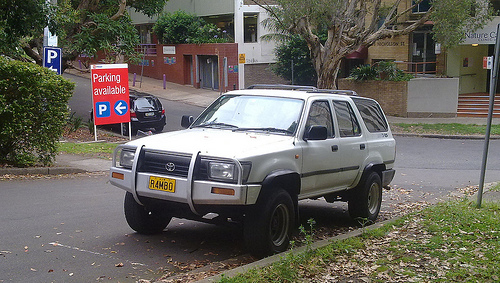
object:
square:
[43, 46, 64, 76]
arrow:
[113, 100, 129, 116]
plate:
[145, 175, 182, 193]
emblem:
[157, 159, 182, 173]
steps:
[452, 108, 500, 117]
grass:
[375, 191, 500, 268]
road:
[35, 178, 79, 261]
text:
[95, 69, 134, 96]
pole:
[475, 72, 492, 224]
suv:
[105, 75, 403, 258]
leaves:
[465, 267, 473, 273]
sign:
[84, 60, 136, 135]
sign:
[39, 44, 65, 81]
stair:
[459, 92, 498, 118]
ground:
[347, 196, 443, 270]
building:
[370, 4, 489, 115]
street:
[412, 142, 459, 165]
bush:
[0, 50, 79, 166]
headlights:
[202, 159, 249, 183]